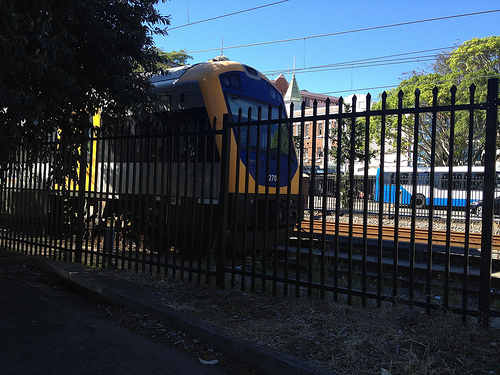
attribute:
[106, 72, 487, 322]
fence — iron, black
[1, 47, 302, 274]
train — grey, blue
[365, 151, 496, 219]
bus — white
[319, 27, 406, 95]
wires — many, overhead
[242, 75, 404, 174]
building — white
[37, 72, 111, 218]
door — yellow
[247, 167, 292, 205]
numbers — whiet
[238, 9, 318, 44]
sky — clear, blue